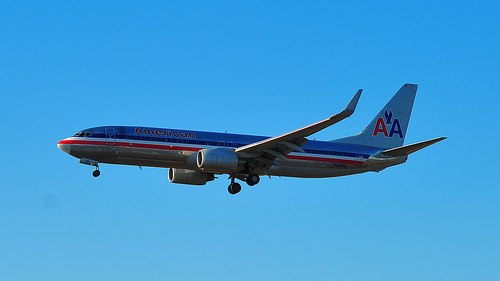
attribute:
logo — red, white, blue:
[371, 107, 403, 139]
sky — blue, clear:
[387, 189, 474, 258]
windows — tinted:
[73, 128, 92, 138]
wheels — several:
[211, 171, 254, 198]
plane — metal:
[28, 70, 472, 202]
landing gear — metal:
[226, 170, 260, 195]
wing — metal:
[237, 117, 344, 152]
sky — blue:
[2, 0, 481, 279]